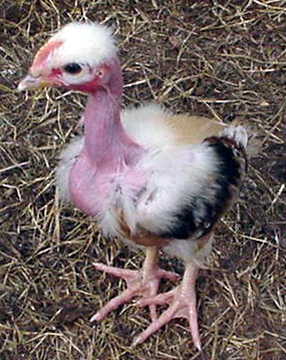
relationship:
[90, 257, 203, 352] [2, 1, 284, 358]
feet in grass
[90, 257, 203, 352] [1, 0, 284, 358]
feet in dirt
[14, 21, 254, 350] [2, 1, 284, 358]
baby turkey standing in grass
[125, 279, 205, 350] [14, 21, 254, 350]
foot of baby turkey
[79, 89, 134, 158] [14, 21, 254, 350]
neck of baby turkey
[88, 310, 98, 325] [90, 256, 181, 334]
nail on end of foot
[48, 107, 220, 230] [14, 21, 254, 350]
fur on baby turkey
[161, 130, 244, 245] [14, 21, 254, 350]
fur on baby turkey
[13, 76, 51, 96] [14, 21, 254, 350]
beak on baby turkey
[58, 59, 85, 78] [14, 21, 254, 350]
eye on baby turkey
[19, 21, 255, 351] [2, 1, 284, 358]
baby turkey standing on grass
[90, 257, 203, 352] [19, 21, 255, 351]
feet of a baby turkey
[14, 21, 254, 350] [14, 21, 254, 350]
baby turkey of a baby turkey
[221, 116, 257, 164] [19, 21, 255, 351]
tail of a baby turkey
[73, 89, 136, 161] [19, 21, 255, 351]
neck of a baby turkey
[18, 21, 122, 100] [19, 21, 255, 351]
head of a baby turkey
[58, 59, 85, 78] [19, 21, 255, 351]
eye of a baby turkey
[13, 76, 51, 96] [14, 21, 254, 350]
beak of a baby turkey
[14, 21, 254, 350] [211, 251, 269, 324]
baby turkey on ground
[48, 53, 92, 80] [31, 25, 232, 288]
eye on duck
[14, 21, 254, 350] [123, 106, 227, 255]
baby turkey with feathers